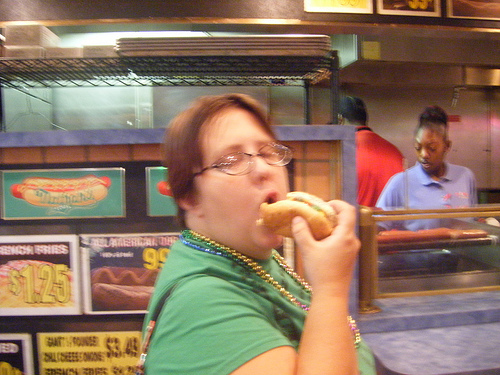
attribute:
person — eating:
[127, 84, 396, 374]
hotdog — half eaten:
[259, 182, 342, 239]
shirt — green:
[130, 234, 381, 374]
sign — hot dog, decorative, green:
[6, 171, 118, 215]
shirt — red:
[352, 125, 404, 201]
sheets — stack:
[3, 19, 115, 54]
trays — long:
[115, 27, 338, 60]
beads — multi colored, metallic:
[180, 219, 368, 348]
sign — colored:
[1, 236, 85, 319]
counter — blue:
[365, 293, 498, 367]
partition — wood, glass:
[360, 202, 499, 299]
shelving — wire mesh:
[16, 51, 345, 87]